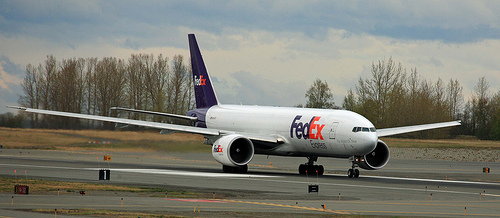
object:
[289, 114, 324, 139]
logo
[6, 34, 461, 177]
airplane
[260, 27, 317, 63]
clouds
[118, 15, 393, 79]
sky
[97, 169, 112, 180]
sign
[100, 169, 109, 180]
1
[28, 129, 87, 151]
grass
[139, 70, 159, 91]
leaves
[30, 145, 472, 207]
road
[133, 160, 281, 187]
lines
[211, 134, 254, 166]
engine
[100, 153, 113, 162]
flags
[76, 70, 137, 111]
row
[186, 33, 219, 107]
tail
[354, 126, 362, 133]
windows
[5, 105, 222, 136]
wing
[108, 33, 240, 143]
back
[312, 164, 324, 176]
wheels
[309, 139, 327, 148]
words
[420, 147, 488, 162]
rocks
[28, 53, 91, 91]
tree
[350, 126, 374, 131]
winshield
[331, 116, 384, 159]
nose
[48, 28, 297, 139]
during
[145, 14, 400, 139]
day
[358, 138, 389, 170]
engines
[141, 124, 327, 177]
groun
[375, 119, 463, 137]
left wing